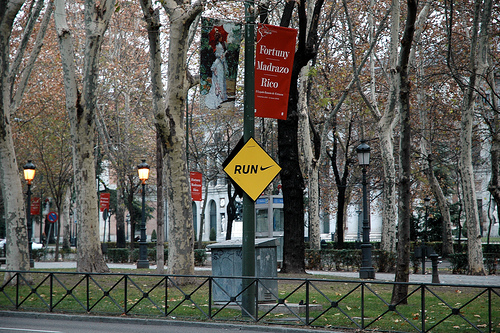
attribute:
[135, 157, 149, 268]
lamp post — lit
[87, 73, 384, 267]
buidling — white, Greek-style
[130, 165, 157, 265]
post — outdoor, black, lighting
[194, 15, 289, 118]
flags — street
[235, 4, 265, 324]
pole — metal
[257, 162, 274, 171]
logo — company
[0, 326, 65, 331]
stripe — white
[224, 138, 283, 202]
sign — black, yellow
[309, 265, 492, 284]
path — gray, concrete, park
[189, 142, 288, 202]
sign — Nike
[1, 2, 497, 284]
trees — tall, white, brown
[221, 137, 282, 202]
advertisement — black, yellow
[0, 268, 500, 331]
railing — black, guard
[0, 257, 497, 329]
gate — black, wrought iron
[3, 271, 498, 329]
grass — green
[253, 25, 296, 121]
sign — red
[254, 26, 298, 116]
sign — white, red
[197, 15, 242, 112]
sign — white, red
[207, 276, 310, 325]
gate — short, black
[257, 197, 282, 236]
booth — telephone's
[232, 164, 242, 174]
letter — R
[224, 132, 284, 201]
sign — yellow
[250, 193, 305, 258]
phone booth — silver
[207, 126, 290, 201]
sign — yellow, black, street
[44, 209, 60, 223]
street sign — round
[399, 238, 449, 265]
bush — short, green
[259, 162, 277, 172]
symbol — Nike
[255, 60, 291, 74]
lettering — white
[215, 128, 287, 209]
sign — yellow, black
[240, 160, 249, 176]
letter — U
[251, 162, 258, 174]
letter — N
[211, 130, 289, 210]
sign — yellow, black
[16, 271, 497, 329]
leaves — fallen